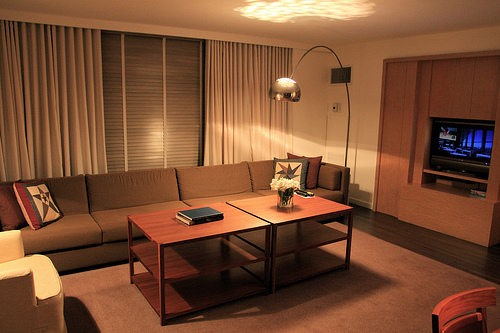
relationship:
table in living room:
[127, 192, 356, 325] [0, 0, 497, 331]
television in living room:
[422, 120, 495, 177] [0, 0, 497, 331]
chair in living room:
[0, 229, 69, 331] [0, 0, 497, 331]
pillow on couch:
[14, 179, 62, 230] [0, 159, 350, 273]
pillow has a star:
[14, 179, 62, 230] [34, 186, 58, 222]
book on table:
[176, 206, 224, 227] [127, 192, 356, 325]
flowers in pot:
[269, 174, 296, 193] [278, 190, 295, 209]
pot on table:
[278, 190, 295, 209] [127, 192, 356, 325]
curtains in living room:
[206, 39, 293, 166] [0, 0, 497, 331]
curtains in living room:
[0, 23, 110, 186] [0, 0, 497, 331]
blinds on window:
[104, 26, 206, 173] [1, 18, 293, 184]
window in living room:
[1, 18, 293, 184] [0, 0, 497, 331]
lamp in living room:
[270, 46, 353, 169] [0, 0, 497, 331]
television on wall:
[422, 120, 495, 177] [372, 53, 499, 244]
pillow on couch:
[270, 156, 309, 189] [0, 159, 350, 273]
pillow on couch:
[289, 153, 322, 188] [0, 159, 350, 273]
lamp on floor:
[270, 46, 353, 169] [61, 221, 498, 332]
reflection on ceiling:
[238, 3, 372, 26] [0, 0, 500, 47]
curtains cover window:
[206, 39, 293, 166] [1, 18, 293, 184]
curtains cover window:
[0, 23, 110, 186] [1, 18, 293, 184]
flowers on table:
[269, 174, 296, 193] [127, 192, 356, 325]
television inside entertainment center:
[422, 120, 495, 177] [372, 53, 499, 244]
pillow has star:
[14, 179, 62, 230] [34, 186, 58, 222]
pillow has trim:
[14, 179, 62, 230] [16, 181, 39, 233]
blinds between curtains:
[104, 26, 206, 173] [206, 39, 293, 166]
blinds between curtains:
[104, 26, 206, 173] [0, 23, 110, 186]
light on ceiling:
[238, 3, 372, 26] [0, 0, 500, 47]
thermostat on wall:
[331, 101, 342, 113] [324, 28, 499, 253]